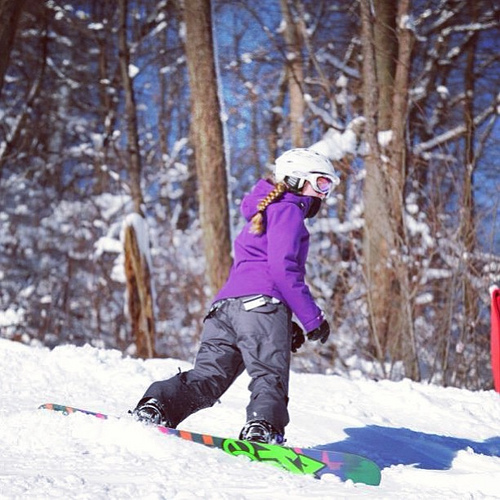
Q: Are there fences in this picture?
A: No, there are no fences.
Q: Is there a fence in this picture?
A: No, there are no fences.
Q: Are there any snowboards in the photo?
A: Yes, there is a snowboard.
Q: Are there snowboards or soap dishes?
A: Yes, there is a snowboard.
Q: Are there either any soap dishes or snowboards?
A: Yes, there is a snowboard.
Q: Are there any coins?
A: No, there are no coins.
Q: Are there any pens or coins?
A: No, there are no coins or pens.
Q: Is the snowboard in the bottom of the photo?
A: Yes, the snowboard is in the bottom of the image.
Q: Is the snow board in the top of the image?
A: No, the snow board is in the bottom of the image.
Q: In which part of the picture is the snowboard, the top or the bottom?
A: The snowboard is in the bottom of the image.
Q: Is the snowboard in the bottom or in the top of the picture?
A: The snowboard is in the bottom of the image.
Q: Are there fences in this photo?
A: No, there are no fences.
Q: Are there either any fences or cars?
A: No, there are no fences or cars.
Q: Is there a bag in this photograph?
A: No, there are no bags.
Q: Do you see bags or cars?
A: No, there are no bags or cars.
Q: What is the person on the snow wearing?
A: The person is wearing trousers.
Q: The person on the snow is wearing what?
A: The person is wearing trousers.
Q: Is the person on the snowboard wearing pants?
A: Yes, the person is wearing pants.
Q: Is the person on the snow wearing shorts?
A: No, the person is wearing pants.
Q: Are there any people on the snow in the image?
A: Yes, there is a person on the snow.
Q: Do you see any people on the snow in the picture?
A: Yes, there is a person on the snow.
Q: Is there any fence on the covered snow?
A: No, there is a person on the snow.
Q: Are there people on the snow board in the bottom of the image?
A: Yes, there is a person on the snowboard.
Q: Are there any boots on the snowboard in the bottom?
A: No, there is a person on the snowboard.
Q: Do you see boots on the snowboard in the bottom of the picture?
A: No, there is a person on the snowboard.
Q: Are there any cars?
A: No, there are no cars.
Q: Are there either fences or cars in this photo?
A: No, there are no cars or fences.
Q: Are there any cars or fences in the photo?
A: No, there are no cars or fences.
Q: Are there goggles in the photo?
A: Yes, there are goggles.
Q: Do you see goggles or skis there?
A: Yes, there are goggles.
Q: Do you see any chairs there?
A: No, there are no chairs.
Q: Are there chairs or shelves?
A: No, there are no chairs or shelves.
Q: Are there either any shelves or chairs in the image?
A: No, there are no chairs or shelves.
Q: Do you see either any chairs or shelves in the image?
A: No, there are no chairs or shelves.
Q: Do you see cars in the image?
A: No, there are no cars.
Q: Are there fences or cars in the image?
A: No, there are no cars or fences.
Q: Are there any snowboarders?
A: Yes, there is a snowboarder.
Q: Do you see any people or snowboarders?
A: Yes, there is a snowboarder.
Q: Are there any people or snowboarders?
A: Yes, there is a snowboarder.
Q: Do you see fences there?
A: No, there are no fences.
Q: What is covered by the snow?
A: The ground is covered by the snow.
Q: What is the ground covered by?
A: The ground is covered by the snow.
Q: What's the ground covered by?
A: The ground is covered by the snow.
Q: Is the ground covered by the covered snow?
A: Yes, the ground is covered by the snow.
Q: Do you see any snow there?
A: Yes, there is snow.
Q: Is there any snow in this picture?
A: Yes, there is snow.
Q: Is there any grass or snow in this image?
A: Yes, there is snow.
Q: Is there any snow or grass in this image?
A: Yes, there is snow.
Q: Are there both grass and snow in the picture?
A: No, there is snow but no grass.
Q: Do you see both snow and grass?
A: No, there is snow but no grass.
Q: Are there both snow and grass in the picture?
A: No, there is snow but no grass.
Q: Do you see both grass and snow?
A: No, there is snow but no grass.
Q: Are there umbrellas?
A: No, there are no umbrellas.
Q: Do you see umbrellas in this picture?
A: No, there are no umbrellas.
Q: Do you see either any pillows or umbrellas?
A: No, there are no umbrellas or pillows.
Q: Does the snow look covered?
A: Yes, the snow is covered.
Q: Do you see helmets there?
A: Yes, there is a helmet.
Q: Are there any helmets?
A: Yes, there is a helmet.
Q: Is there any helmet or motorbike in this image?
A: Yes, there is a helmet.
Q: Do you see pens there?
A: No, there are no pens.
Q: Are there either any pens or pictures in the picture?
A: No, there are no pens or pictures.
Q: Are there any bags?
A: No, there are no bags.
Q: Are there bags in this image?
A: No, there are no bags.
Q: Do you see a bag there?
A: No, there are no bags.